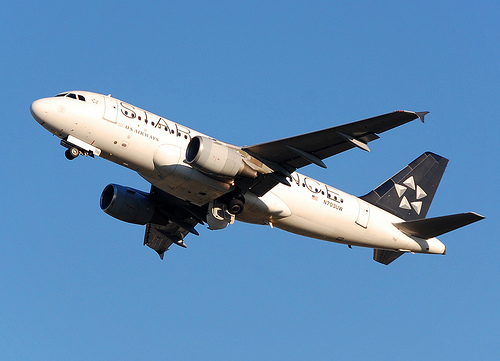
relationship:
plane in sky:
[30, 89, 487, 266] [4, 2, 499, 360]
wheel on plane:
[228, 200, 243, 215] [30, 89, 487, 266]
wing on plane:
[246, 111, 427, 164] [30, 89, 487, 266]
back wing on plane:
[404, 212, 486, 241] [30, 89, 487, 266]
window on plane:
[125, 112, 130, 118] [30, 89, 487, 266]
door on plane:
[110, 100, 120, 117] [30, 89, 487, 266]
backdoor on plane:
[361, 205, 373, 219] [30, 89, 487, 266]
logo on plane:
[122, 101, 197, 140] [30, 89, 487, 266]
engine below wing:
[187, 136, 252, 183] [246, 111, 427, 164]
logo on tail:
[392, 175, 427, 213] [368, 152, 449, 221]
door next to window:
[110, 100, 120, 117] [125, 112, 130, 118]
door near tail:
[362, 203, 371, 216] [368, 152, 449, 221]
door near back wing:
[362, 203, 371, 216] [404, 212, 486, 241]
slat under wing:
[341, 131, 376, 155] [246, 111, 427, 164]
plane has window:
[30, 89, 487, 266] [125, 112, 130, 118]